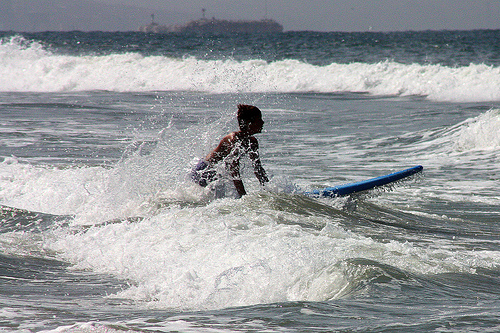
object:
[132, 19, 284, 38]
island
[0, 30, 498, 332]
water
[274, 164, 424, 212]
surfboard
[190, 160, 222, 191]
suit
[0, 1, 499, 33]
sky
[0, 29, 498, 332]
ocean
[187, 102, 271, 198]
boy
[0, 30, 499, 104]
swell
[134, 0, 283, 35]
freighter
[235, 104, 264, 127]
hair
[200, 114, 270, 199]
skin